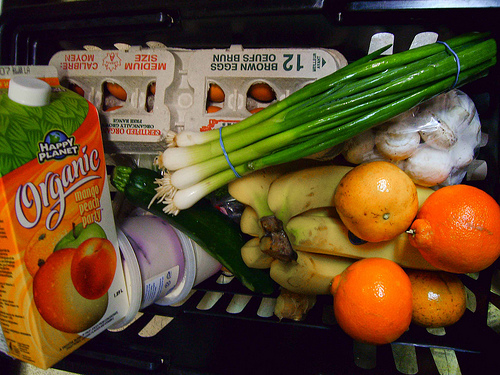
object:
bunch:
[226, 161, 437, 296]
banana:
[267, 165, 436, 228]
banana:
[269, 251, 358, 295]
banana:
[239, 206, 330, 238]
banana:
[239, 237, 274, 270]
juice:
[0, 63, 133, 370]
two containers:
[106, 216, 223, 330]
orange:
[405, 184, 500, 274]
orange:
[329, 257, 412, 344]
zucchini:
[109, 166, 278, 295]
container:
[214, 321, 292, 371]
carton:
[47, 41, 348, 162]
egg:
[251, 84, 273, 101]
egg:
[210, 84, 225, 102]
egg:
[107, 82, 127, 100]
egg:
[150, 83, 155, 94]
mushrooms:
[343, 89, 482, 188]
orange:
[406, 271, 466, 327]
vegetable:
[374, 122, 420, 163]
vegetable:
[414, 108, 458, 151]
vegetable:
[402, 144, 455, 189]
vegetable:
[146, 33, 496, 216]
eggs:
[46, 40, 348, 158]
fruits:
[228, 166, 441, 295]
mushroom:
[433, 90, 476, 133]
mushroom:
[449, 139, 474, 167]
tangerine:
[328, 257, 414, 345]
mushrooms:
[341, 129, 375, 164]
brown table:
[104, 45, 306, 142]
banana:
[285, 207, 441, 270]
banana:
[228, 162, 292, 233]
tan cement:
[149, 117, 274, 219]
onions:
[147, 33, 497, 216]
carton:
[0, 65, 129, 371]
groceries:
[0, 33, 500, 371]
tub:
[117, 214, 184, 330]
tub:
[155, 224, 222, 306]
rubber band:
[219, 126, 243, 178]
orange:
[334, 161, 418, 243]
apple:
[53, 222, 108, 253]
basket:
[0, 0, 500, 373]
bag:
[378, 89, 482, 181]